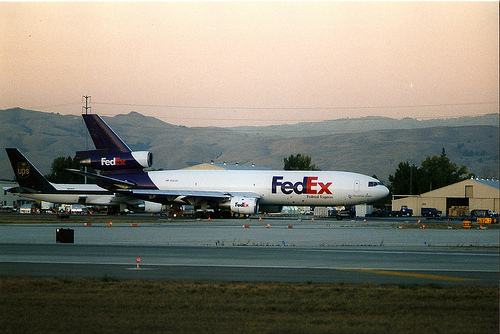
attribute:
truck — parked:
[390, 204, 415, 219]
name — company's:
[262, 169, 335, 208]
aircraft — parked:
[27, 100, 434, 250]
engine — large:
[87, 147, 164, 166]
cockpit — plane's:
[354, 177, 386, 194]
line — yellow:
[363, 267, 481, 283]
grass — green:
[118, 263, 349, 321]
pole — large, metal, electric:
[78, 92, 95, 117]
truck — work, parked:
[387, 202, 419, 220]